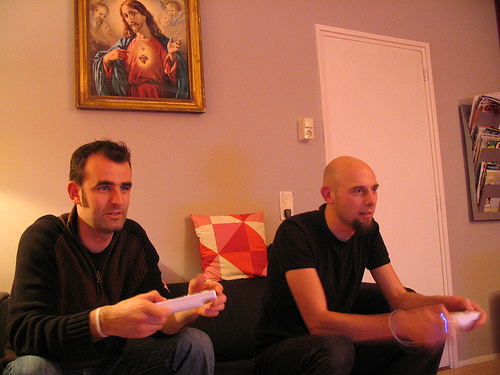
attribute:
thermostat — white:
[295, 114, 315, 147]